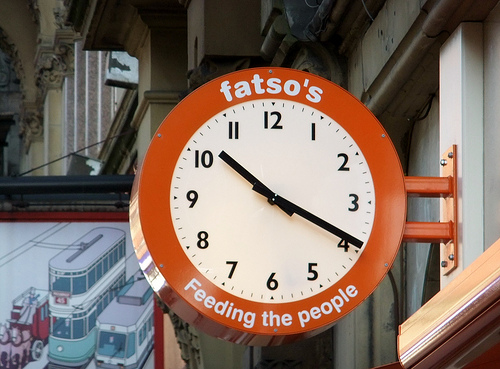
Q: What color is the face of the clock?
A: White.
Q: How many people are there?
A: None.